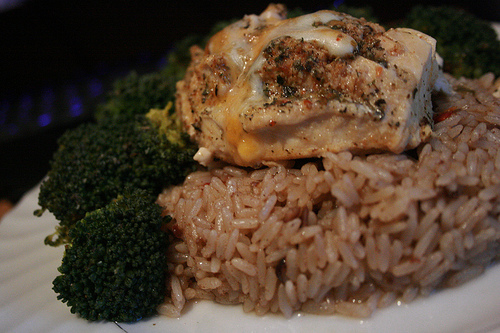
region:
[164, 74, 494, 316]
bunch of rice in a plate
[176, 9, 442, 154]
slice of cooked chicken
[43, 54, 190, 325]
broccoli trees in white plate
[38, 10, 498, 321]
lunch served in white plate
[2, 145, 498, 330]
white plate where food is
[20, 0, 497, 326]
balanced food served in white plate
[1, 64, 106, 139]
blue fire in burner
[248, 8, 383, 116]
seasoning of chicken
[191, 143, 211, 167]
little chicken bone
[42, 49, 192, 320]
dark green broccoli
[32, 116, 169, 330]
Broccoli on a plate.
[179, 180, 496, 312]
Rice on a plate.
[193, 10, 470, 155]
Chicken served on a plate.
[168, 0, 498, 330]
Chicken over rice.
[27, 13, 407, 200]
Chicken with broccoli and rice.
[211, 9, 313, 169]
Melted cheese on chicken.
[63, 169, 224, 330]
Green healthy vegetables.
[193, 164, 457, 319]
Brown rice served on a white plate.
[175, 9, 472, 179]
Chicken with herbs.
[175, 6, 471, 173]
chicken with breadcrumb topping.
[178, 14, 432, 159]
a piece of grilled chicken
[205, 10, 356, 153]
cheese on top of the chicken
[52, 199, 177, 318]
a piece of green brocolli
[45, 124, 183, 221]
a piece of green brocolli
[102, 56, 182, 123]
a piece of green brocolli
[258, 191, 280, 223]
a piece of brown rice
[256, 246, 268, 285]
a piece of brown rice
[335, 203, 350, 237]
a piece of brown rice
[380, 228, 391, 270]
a piece of brown rice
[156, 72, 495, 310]
A lot of rice.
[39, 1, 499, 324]
The broccoli is green.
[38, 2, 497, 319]
The broccoli is uncooked.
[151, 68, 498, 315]
The rice is light brown.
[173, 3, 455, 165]
The meat is white.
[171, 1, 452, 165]
The meat has been cooked.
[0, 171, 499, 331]
The plate is white.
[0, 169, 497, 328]
the plate is round.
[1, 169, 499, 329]
The plate is made of glass.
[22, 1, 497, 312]
chicken with broccoli on a bed of rice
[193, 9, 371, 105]
melted cheese on the chicken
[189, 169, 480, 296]
brown rice next to the broccoli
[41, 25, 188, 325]
green broccoli on the left side of the plate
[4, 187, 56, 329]
the plate is white with fluted edges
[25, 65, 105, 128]
three blue lights emitting light in the dark background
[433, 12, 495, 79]
broccoli floret that is behind the rice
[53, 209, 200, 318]
foremost green broccoli floret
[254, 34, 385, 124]
crispy brown seasoning crust on the chicken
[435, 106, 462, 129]
red seasoning flake on the rice